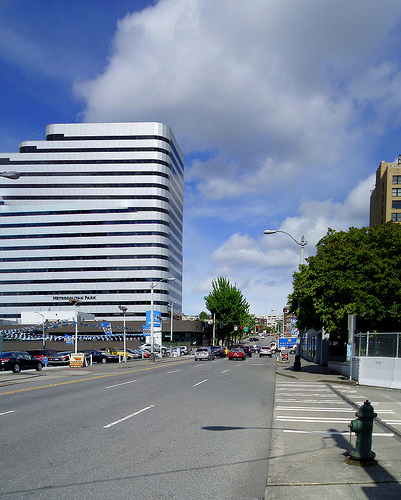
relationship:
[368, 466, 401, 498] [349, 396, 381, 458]
shadow of fire hydrant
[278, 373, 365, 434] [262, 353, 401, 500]
crosswalk across sidewalk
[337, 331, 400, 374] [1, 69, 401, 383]
fence in background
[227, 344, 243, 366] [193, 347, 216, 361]
car in cars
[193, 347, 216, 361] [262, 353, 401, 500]
cars on sidewalk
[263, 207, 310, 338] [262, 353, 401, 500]
light pole across sidewalk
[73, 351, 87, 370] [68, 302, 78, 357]
sign on pole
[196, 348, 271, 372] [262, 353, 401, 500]
cars on sidewalk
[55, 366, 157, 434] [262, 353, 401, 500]
lines on sidewalk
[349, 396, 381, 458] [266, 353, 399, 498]
fire hydrant on sidewalk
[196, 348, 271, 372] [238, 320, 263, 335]
cars at light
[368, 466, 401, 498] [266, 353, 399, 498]
shadow on sidewalk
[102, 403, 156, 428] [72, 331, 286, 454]
lines on road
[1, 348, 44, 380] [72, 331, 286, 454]
car on road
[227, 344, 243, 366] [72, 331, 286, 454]
car on road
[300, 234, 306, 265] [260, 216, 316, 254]
light pole of street light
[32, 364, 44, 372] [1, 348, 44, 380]
wheel of car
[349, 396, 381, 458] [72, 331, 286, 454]
fire hydrant on side of road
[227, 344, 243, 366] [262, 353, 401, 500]
car in sidewalk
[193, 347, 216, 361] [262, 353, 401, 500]
cars in sidewalk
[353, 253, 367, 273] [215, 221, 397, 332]
leaves on trees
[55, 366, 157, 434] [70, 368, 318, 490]
lines on concrete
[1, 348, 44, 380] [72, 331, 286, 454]
car on side of road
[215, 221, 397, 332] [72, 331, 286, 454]
trees line side of road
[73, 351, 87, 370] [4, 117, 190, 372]
sign of honda dealership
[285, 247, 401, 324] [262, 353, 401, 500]
tree near sidewalk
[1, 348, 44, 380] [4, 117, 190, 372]
car at honda dealership